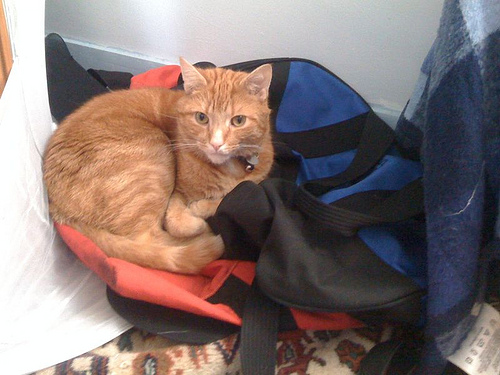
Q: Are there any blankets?
A: Yes, there is a blanket.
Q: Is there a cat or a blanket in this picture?
A: Yes, there is a blanket.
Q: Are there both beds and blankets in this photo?
A: No, there is a blanket but no beds.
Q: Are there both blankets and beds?
A: No, there is a blanket but no beds.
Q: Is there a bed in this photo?
A: No, there are no beds.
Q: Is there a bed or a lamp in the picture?
A: No, there are no beds or lamps.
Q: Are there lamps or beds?
A: No, there are no beds or lamps.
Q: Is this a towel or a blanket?
A: This is a blanket.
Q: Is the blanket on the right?
A: Yes, the blanket is on the right of the image.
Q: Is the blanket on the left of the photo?
A: No, the blanket is on the right of the image.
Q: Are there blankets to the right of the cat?
A: Yes, there is a blanket to the right of the cat.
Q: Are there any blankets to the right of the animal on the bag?
A: Yes, there is a blanket to the right of the cat.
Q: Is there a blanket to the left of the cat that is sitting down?
A: No, the blanket is to the right of the cat.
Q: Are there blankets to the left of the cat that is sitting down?
A: No, the blanket is to the right of the cat.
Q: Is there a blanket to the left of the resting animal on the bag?
A: No, the blanket is to the right of the cat.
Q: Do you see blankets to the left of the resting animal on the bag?
A: No, the blanket is to the right of the cat.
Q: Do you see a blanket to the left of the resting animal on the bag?
A: No, the blanket is to the right of the cat.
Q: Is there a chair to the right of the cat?
A: No, there is a blanket to the right of the cat.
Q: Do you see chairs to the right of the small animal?
A: No, there is a blanket to the right of the cat.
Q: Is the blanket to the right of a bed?
A: No, the blanket is to the right of a cat.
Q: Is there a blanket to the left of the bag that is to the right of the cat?
A: No, the blanket is to the right of the bag.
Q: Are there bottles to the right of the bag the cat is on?
A: No, there is a blanket to the right of the bag.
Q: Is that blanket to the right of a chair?
A: No, the blanket is to the right of the bag.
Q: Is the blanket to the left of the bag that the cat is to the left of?
A: No, the blanket is to the right of the bag.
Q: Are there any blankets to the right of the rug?
A: Yes, there is a blanket to the right of the rug.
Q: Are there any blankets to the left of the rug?
A: No, the blanket is to the right of the rug.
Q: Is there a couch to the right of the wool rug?
A: No, there is a blanket to the right of the rug.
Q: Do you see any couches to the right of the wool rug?
A: No, there is a blanket to the right of the rug.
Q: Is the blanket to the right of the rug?
A: Yes, the blanket is to the right of the rug.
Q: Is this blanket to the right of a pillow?
A: No, the blanket is to the right of the rug.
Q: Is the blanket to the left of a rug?
A: No, the blanket is to the right of a rug.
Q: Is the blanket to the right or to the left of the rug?
A: The blanket is to the right of the rug.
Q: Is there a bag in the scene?
A: Yes, there is a bag.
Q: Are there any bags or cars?
A: Yes, there is a bag.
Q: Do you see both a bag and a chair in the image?
A: No, there is a bag but no chairs.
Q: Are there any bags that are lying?
A: Yes, there is a bag that is lying.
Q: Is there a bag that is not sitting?
A: Yes, there is a bag that is lying.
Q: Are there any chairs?
A: No, there are no chairs.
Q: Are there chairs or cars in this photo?
A: No, there are no chairs or cars.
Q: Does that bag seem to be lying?
A: Yes, the bag is lying.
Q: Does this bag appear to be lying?
A: Yes, the bag is lying.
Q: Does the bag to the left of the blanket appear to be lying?
A: Yes, the bag is lying.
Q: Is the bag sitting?
A: No, the bag is lying.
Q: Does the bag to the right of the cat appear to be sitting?
A: No, the bag is lying.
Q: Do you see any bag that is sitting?
A: No, there is a bag but it is lying.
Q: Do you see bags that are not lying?
A: No, there is a bag but it is lying.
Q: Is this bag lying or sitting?
A: The bag is lying.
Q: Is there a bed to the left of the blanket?
A: No, there is a bag to the left of the blanket.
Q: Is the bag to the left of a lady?
A: No, the bag is to the left of the blanket.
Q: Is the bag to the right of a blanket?
A: No, the bag is to the left of a blanket.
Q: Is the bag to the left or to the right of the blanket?
A: The bag is to the left of the blanket.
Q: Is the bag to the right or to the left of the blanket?
A: The bag is to the left of the blanket.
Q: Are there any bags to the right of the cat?
A: Yes, there is a bag to the right of the cat.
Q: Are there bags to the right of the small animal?
A: Yes, there is a bag to the right of the cat.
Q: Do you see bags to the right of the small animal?
A: Yes, there is a bag to the right of the cat.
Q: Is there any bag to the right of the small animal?
A: Yes, there is a bag to the right of the cat.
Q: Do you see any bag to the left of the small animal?
A: No, the bag is to the right of the cat.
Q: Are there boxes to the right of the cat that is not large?
A: No, there is a bag to the right of the cat.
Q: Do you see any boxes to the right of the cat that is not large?
A: No, there is a bag to the right of the cat.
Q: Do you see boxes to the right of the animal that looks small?
A: No, there is a bag to the right of the cat.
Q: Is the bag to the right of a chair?
A: No, the bag is to the right of the cat.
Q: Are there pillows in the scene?
A: No, there are no pillows.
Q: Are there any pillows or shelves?
A: No, there are no pillows or shelves.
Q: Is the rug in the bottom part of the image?
A: Yes, the rug is in the bottom of the image.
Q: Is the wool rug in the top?
A: No, the rug is in the bottom of the image.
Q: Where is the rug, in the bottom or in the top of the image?
A: The rug is in the bottom of the image.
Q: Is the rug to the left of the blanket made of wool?
A: Yes, the rug is made of wool.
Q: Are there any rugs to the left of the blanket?
A: Yes, there is a rug to the left of the blanket.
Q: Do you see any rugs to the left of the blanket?
A: Yes, there is a rug to the left of the blanket.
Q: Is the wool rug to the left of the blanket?
A: Yes, the rug is to the left of the blanket.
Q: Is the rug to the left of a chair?
A: No, the rug is to the left of the blanket.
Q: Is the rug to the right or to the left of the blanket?
A: The rug is to the left of the blanket.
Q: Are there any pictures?
A: No, there are no pictures.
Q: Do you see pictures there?
A: No, there are no pictures.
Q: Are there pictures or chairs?
A: No, there are no pictures or chairs.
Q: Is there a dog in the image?
A: No, there are no dogs.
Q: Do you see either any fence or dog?
A: No, there are no dogs or fences.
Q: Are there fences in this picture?
A: No, there are no fences.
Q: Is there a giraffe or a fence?
A: No, there are no fences or giraffes.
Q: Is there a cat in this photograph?
A: Yes, there is a cat.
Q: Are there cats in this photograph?
A: Yes, there is a cat.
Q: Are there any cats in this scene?
A: Yes, there is a cat.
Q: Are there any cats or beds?
A: Yes, there is a cat.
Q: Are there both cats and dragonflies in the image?
A: No, there is a cat but no dragonflies.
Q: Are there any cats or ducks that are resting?
A: Yes, the cat is resting.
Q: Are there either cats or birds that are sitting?
A: Yes, the cat is sitting.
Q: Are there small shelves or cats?
A: Yes, there is a small cat.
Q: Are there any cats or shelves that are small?
A: Yes, the cat is small.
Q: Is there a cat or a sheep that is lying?
A: Yes, the cat is lying.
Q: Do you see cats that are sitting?
A: Yes, there is a cat that is sitting.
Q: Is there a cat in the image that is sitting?
A: Yes, there is a cat that is sitting.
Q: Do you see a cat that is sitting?
A: Yes, there is a cat that is sitting.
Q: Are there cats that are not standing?
A: Yes, there is a cat that is sitting.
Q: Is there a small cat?
A: Yes, there is a small cat.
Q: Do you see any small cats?
A: Yes, there is a small cat.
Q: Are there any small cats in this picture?
A: Yes, there is a small cat.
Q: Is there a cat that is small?
A: Yes, there is a cat that is small.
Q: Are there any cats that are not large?
A: Yes, there is a small cat.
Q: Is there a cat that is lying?
A: Yes, there is a cat that is lying.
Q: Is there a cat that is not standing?
A: Yes, there is a cat that is lying.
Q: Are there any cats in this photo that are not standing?
A: Yes, there is a cat that is lying.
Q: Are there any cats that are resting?
A: Yes, there is a cat that is resting.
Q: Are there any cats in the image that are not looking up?
A: Yes, there is a cat that is resting.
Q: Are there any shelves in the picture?
A: No, there are no shelves.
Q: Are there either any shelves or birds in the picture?
A: No, there are no shelves or birds.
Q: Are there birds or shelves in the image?
A: No, there are no shelves or birds.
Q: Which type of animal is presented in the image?
A: The animal is a cat.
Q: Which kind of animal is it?
A: The animal is a cat.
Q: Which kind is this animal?
A: This is a cat.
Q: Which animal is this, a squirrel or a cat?
A: This is a cat.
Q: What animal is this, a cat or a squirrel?
A: This is a cat.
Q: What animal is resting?
A: The animal is a cat.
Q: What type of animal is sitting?
A: The animal is a cat.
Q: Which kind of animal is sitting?
A: The animal is a cat.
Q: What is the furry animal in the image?
A: The animal is a cat.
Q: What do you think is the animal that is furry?
A: The animal is a cat.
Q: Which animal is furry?
A: The animal is a cat.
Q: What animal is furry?
A: The animal is a cat.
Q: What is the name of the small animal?
A: The animal is a cat.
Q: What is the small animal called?
A: The animal is a cat.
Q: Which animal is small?
A: The animal is a cat.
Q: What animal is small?
A: The animal is a cat.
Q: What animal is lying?
A: The animal is a cat.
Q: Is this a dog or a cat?
A: This is a cat.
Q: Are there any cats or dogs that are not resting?
A: No, there is a cat but it is resting.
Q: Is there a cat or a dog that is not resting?
A: No, there is a cat but it is resting.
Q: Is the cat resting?
A: Yes, the cat is resting.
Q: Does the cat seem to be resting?
A: Yes, the cat is resting.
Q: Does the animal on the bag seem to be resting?
A: Yes, the cat is resting.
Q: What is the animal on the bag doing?
A: The cat is resting.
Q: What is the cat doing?
A: The cat is resting.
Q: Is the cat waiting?
A: No, the cat is resting.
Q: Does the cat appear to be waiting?
A: No, the cat is resting.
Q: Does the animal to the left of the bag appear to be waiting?
A: No, the cat is resting.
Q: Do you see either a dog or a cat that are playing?
A: No, there is a cat but it is resting.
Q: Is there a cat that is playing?
A: No, there is a cat but it is resting.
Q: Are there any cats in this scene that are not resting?
A: No, there is a cat but it is resting.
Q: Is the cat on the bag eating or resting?
A: The cat is resting.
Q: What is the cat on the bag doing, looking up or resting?
A: The cat is resting.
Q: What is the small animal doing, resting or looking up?
A: The cat is resting.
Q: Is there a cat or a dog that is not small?
A: No, there is a cat but it is small.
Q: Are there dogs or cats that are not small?
A: No, there is a cat but it is small.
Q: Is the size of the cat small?
A: Yes, the cat is small.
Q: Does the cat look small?
A: Yes, the cat is small.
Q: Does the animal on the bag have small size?
A: Yes, the cat is small.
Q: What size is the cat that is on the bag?
A: The cat is small.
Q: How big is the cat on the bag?
A: The cat is small.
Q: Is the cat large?
A: No, the cat is small.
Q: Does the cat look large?
A: No, the cat is small.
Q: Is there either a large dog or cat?
A: No, there is a cat but it is small.